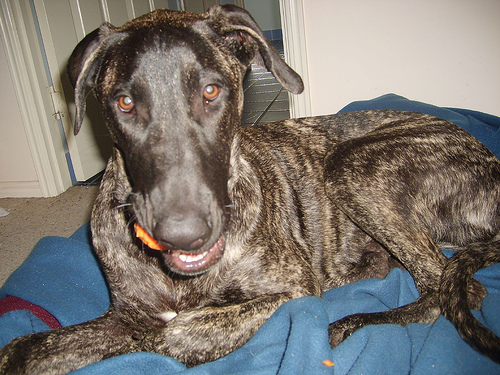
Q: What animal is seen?
A: Dog.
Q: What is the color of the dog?
A: Black.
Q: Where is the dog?
A: In the floor.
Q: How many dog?
A: 1.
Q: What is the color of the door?
A: White.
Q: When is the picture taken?
A: Night time.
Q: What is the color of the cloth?
A: Blue.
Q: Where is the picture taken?
A: In the bedroom.